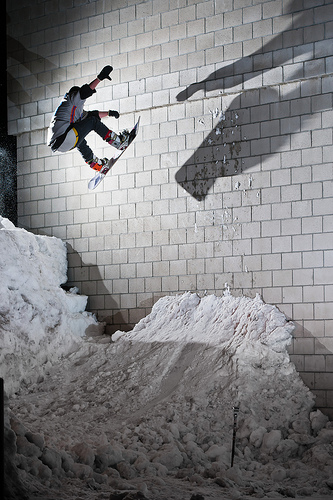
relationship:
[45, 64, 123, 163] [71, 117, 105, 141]
man wears gray pants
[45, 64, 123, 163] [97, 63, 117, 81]
man wears glove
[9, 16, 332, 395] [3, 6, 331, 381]
brick on wall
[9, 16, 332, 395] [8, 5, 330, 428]
brick on wall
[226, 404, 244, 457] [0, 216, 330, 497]
pole stuck inside of snow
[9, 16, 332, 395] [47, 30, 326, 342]
brick on wall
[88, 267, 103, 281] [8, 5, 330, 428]
brick on wall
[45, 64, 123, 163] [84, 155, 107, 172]
man has boot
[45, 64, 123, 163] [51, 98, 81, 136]
man wearing a shirt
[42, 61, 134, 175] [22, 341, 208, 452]
snowboarder riding on snow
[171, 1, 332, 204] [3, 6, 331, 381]
shadow on wall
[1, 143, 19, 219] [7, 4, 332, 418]
tree on side of building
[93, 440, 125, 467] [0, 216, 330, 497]
clump of snow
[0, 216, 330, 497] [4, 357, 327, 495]
snow on ground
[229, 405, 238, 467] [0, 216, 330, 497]
stick in snow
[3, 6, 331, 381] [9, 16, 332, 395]
wall made of brick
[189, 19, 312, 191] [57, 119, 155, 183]
shadow of snowboarder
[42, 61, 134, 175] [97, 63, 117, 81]
snowboarder has glove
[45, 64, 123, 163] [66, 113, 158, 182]
man on snow board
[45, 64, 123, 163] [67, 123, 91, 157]
man wearing belt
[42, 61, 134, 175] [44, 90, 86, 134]
snowboarder wearing shirt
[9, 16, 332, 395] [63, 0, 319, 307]
brick on wall